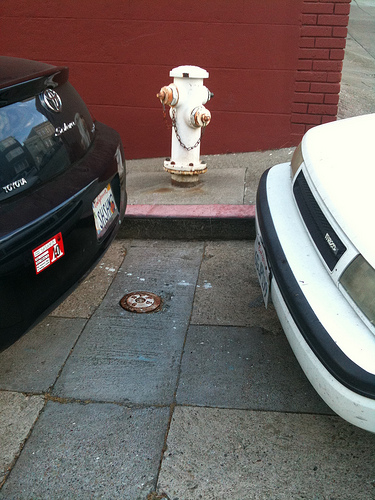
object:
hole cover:
[118, 290, 161, 315]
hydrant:
[155, 64, 214, 189]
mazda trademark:
[323, 232, 337, 253]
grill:
[290, 168, 348, 275]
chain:
[161, 104, 207, 152]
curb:
[114, 203, 258, 242]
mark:
[1, 176, 27, 195]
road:
[0, 238, 375, 500]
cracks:
[0, 395, 49, 490]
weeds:
[0, 391, 53, 491]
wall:
[0, 0, 353, 160]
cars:
[251, 112, 375, 436]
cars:
[0, 53, 129, 355]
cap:
[156, 90, 165, 102]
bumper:
[253, 160, 374, 437]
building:
[0, 0, 351, 160]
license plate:
[91, 182, 119, 243]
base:
[161, 158, 207, 178]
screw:
[189, 162, 193, 166]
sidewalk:
[115, 147, 298, 239]